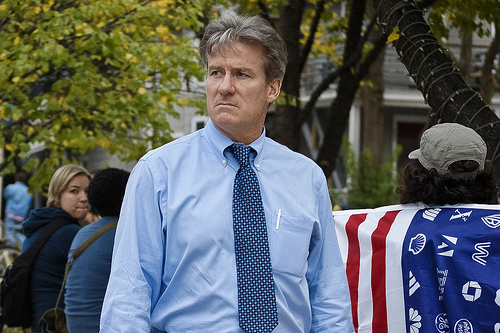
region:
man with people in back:
[87, 8, 388, 323]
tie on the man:
[220, 133, 278, 332]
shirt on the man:
[106, 119, 361, 326]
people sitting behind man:
[4, 163, 114, 319]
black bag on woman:
[0, 205, 60, 332]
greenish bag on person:
[31, 226, 103, 329]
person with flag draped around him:
[329, 138, 499, 323]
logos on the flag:
[404, 212, 489, 329]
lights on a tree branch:
[376, 12, 487, 135]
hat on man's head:
[410, 116, 480, 174]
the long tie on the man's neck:
[231, 143, 278, 331]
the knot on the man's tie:
[230, 146, 250, 166]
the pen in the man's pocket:
[275, 207, 282, 229]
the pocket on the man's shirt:
[267, 213, 312, 277]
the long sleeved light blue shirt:
[100, 116, 356, 331]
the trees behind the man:
[0, 0, 497, 207]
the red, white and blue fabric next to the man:
[329, 202, 499, 331]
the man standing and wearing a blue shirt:
[98, 8, 357, 330]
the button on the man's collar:
[220, 158, 225, 163]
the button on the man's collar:
[255, 163, 260, 169]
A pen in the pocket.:
[262, 200, 298, 228]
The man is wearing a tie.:
[229, 154, 275, 316]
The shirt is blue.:
[127, 180, 218, 260]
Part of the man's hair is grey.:
[191, 16, 257, 60]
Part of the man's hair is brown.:
[254, 47, 300, 81]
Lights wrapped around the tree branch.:
[413, 51, 490, 118]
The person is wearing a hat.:
[402, 125, 499, 173]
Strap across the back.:
[48, 227, 112, 258]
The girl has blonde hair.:
[29, 165, 93, 202]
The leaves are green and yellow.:
[8, 0, 174, 66]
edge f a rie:
[207, 227, 249, 292]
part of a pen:
[251, 185, 293, 255]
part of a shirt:
[198, 234, 234, 269]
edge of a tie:
[231, 245, 246, 278]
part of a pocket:
[279, 215, 306, 247]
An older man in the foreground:
[85, 0, 377, 332]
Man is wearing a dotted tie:
[216, 132, 293, 332]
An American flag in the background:
[324, 197, 499, 329]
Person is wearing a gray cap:
[398, 120, 490, 187]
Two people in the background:
[4, 156, 135, 331]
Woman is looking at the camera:
[43, 158, 95, 230]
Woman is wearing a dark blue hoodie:
[7, 200, 82, 332]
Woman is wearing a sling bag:
[3, 203, 80, 330]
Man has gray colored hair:
[194, 2, 294, 142]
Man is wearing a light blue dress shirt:
[95, 118, 361, 331]